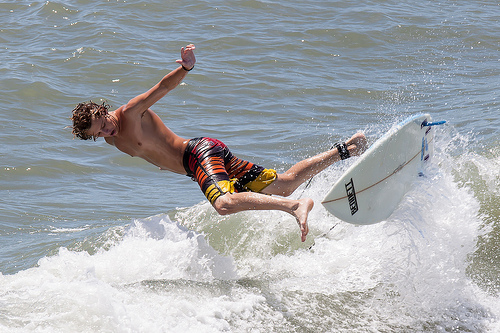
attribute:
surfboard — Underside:
[316, 110, 441, 232]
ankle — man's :
[336, 142, 352, 161]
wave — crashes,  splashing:
[154, 130, 499, 264]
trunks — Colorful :
[179, 132, 271, 222]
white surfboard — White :
[322, 110, 434, 226]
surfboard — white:
[294, 66, 479, 276]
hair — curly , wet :
[62, 94, 119, 143]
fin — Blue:
[420, 113, 443, 131]